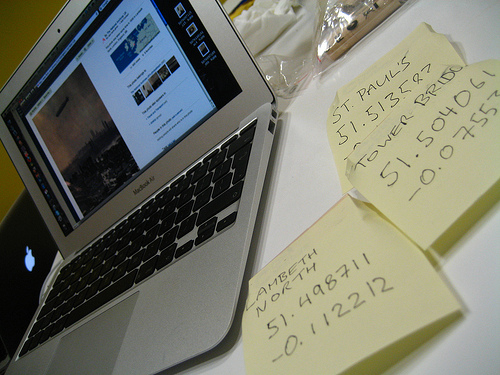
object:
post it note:
[239, 193, 462, 374]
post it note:
[349, 60, 499, 252]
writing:
[332, 51, 418, 128]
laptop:
[0, 0, 278, 374]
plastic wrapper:
[262, 2, 407, 92]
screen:
[1, 0, 244, 235]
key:
[215, 211, 236, 232]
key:
[196, 179, 243, 227]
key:
[155, 255, 176, 270]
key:
[174, 239, 192, 258]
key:
[135, 254, 159, 283]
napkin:
[229, 0, 319, 67]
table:
[154, 0, 500, 374]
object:
[322, 0, 404, 62]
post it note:
[328, 21, 464, 191]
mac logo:
[23, 245, 37, 272]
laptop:
[0, 189, 58, 363]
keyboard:
[18, 116, 258, 356]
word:
[245, 245, 317, 315]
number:
[265, 318, 279, 339]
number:
[284, 332, 298, 356]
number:
[299, 293, 313, 306]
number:
[311, 283, 325, 296]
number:
[325, 273, 338, 292]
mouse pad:
[48, 289, 138, 374]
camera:
[55, 27, 62, 35]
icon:
[57, 215, 64, 221]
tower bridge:
[354, 63, 468, 172]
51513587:
[338, 63, 433, 148]